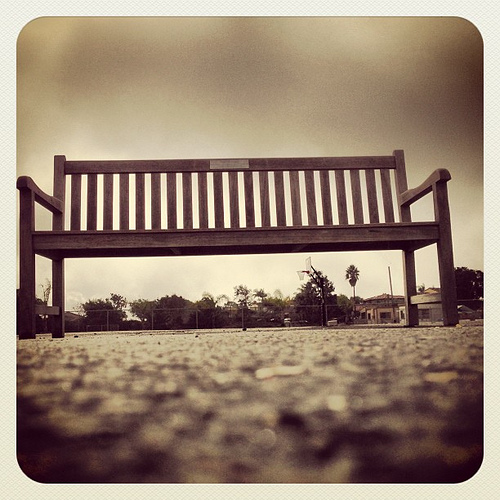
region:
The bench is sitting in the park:
[37, 121, 464, 276]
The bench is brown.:
[31, 114, 478, 349]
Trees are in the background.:
[104, 289, 379, 333]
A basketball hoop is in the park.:
[292, 256, 345, 331]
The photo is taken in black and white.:
[49, 47, 455, 389]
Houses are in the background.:
[331, 280, 429, 335]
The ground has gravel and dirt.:
[126, 320, 474, 452]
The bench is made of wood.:
[34, 147, 414, 235]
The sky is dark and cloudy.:
[128, 34, 415, 148]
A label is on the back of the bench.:
[197, 142, 281, 179]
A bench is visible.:
[92, 118, 379, 368]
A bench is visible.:
[65, 134, 302, 479]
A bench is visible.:
[128, 152, 292, 342]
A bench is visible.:
[101, 11, 286, 301]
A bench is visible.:
[191, 204, 372, 295]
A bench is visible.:
[88, 214, 300, 374]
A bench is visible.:
[65, 64, 223, 275]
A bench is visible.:
[175, 225, 336, 367]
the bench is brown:
[31, 155, 461, 320]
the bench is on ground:
[26, 125, 466, 342]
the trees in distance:
[85, 282, 332, 332]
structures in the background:
[362, 275, 454, 325]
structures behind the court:
[265, 265, 450, 326]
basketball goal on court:
[280, 258, 351, 328]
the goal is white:
[295, 257, 318, 277]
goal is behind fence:
[250, 260, 351, 320]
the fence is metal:
[136, 305, 311, 326]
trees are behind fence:
[172, 287, 300, 324]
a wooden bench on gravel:
[16, 119, 479, 333]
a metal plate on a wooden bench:
[208, 155, 254, 172]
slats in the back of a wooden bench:
[79, 176, 386, 219]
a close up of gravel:
[79, 337, 417, 457]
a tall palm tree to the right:
[341, 262, 359, 293]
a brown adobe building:
[351, 293, 408, 323]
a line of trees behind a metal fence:
[93, 293, 303, 324]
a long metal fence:
[72, 307, 316, 329]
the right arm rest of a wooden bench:
[403, 170, 453, 204]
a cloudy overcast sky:
[42, 87, 224, 129]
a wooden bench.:
[9, 154, 466, 329]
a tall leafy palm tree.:
[340, 265, 363, 307]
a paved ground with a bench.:
[14, 322, 480, 487]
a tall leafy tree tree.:
[288, 249, 341, 324]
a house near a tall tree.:
[340, 277, 408, 329]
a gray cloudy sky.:
[18, 17, 482, 292]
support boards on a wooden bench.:
[65, 168, 389, 235]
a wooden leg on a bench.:
[434, 240, 464, 330]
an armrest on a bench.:
[10, 168, 71, 232]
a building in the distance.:
[390, 289, 445, 316]